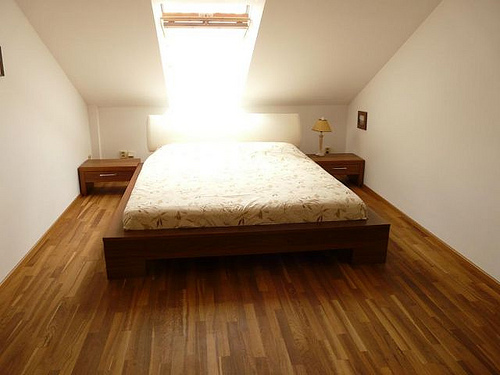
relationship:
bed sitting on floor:
[104, 113, 389, 283] [2, 174, 500, 374]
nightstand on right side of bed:
[77, 157, 137, 196] [104, 113, 389, 283]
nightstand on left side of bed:
[306, 154, 366, 184] [104, 113, 389, 283]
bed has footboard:
[104, 113, 389, 283] [101, 221, 396, 280]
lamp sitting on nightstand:
[313, 117, 334, 157] [306, 154, 366, 184]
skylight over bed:
[154, 3, 264, 103] [104, 113, 389, 283]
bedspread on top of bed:
[124, 139, 368, 227] [104, 113, 389, 283]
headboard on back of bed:
[147, 112, 302, 145] [104, 113, 389, 283]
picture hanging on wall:
[355, 109, 371, 134] [344, 0, 500, 281]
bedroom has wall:
[1, 2, 499, 374] [88, 101, 349, 159]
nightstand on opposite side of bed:
[77, 157, 137, 196] [104, 113, 389, 283]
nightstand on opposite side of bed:
[306, 154, 366, 184] [104, 113, 389, 283]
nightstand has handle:
[77, 157, 137, 196] [98, 171, 115, 178]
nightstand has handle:
[306, 154, 366, 184] [333, 165, 347, 170]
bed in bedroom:
[104, 113, 389, 283] [1, 2, 499, 374]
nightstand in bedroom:
[77, 157, 137, 196] [1, 2, 499, 374]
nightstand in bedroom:
[306, 154, 366, 184] [1, 2, 499, 374]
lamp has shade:
[313, 117, 334, 157] [312, 117, 331, 131]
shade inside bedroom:
[312, 117, 331, 131] [1, 2, 499, 374]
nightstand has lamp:
[306, 154, 366, 184] [313, 117, 334, 157]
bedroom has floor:
[1, 2, 499, 374] [2, 174, 500, 374]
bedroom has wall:
[1, 2, 499, 374] [2, 1, 95, 300]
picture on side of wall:
[355, 109, 371, 134] [344, 0, 500, 281]